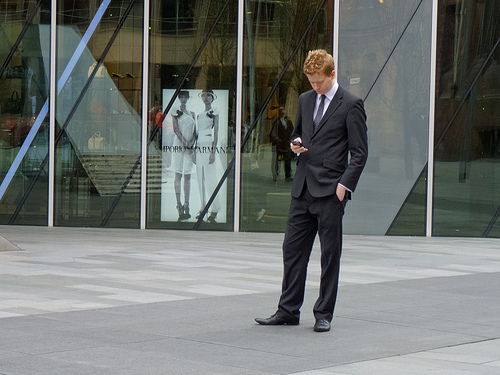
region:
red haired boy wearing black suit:
[255, 41, 372, 334]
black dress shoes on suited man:
[252, 305, 337, 333]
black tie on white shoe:
[310, 89, 334, 135]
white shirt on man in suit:
[308, 79, 347, 136]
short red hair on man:
[298, 45, 340, 99]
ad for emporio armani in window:
[152, 83, 234, 228]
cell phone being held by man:
[283, 138, 310, 160]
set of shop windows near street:
[8, 8, 498, 240]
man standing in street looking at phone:
[254, 45, 372, 334]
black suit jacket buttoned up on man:
[280, 84, 370, 200]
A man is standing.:
[241, 46, 386, 337]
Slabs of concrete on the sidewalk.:
[0, 228, 499, 373]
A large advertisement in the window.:
[160, 86, 230, 223]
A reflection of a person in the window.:
[266, 96, 292, 182]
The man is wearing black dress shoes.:
[253, 305, 334, 335]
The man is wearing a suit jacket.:
[283, 85, 369, 196]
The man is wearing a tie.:
[311, 95, 324, 120]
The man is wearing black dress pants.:
[276, 191, 343, 314]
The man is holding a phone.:
[290, 135, 305, 152]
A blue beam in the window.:
[0, 1, 110, 227]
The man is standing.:
[248, 38, 382, 348]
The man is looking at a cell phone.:
[252, 44, 372, 339]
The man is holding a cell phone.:
[255, 42, 375, 341]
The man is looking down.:
[278, 42, 373, 207]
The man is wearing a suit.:
[253, 35, 376, 342]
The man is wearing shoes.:
[241, 45, 375, 345]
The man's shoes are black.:
[248, 46, 373, 336]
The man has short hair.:
[294, 43, 351, 110]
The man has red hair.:
[296, 44, 348, 102]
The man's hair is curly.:
[296, 45, 349, 109]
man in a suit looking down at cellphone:
[253, 47, 372, 336]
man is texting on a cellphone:
[257, 46, 369, 338]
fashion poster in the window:
[158, 83, 233, 225]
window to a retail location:
[144, 1, 239, 229]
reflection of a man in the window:
[269, 103, 293, 184]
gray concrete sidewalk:
[1, 232, 492, 369]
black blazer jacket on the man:
[275, 86, 365, 200]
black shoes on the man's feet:
[251, 303, 332, 334]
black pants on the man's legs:
[278, 186, 345, 319]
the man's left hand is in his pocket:
[335, 178, 349, 207]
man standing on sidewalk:
[254, 43, 368, 334]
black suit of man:
[267, 88, 367, 320]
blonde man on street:
[251, 48, 373, 329]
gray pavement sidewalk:
[2, 228, 489, 373]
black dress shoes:
[257, 313, 334, 330]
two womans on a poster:
[162, 88, 229, 220]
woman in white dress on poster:
[167, 87, 198, 217]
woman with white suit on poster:
[191, 87, 221, 222]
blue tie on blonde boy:
[310, 95, 328, 126]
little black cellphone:
[292, 135, 306, 153]